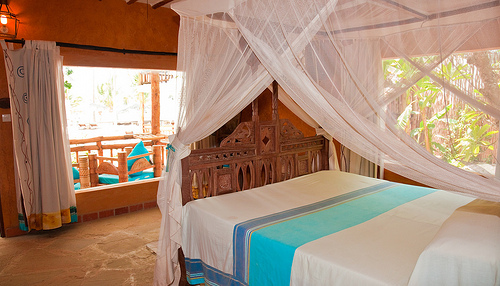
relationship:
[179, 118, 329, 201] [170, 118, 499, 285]
foot of a bed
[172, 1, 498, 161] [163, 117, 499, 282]
curtins draped over a bed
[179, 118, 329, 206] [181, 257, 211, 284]
foot of frame